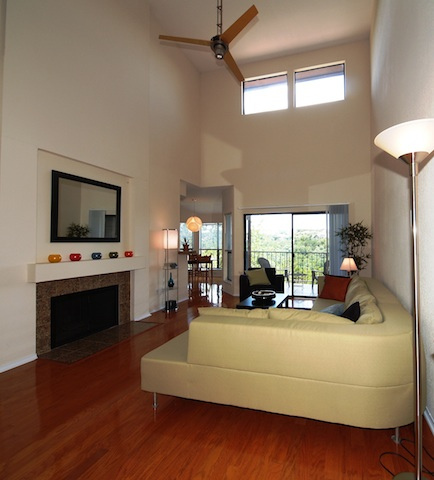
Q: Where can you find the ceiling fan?
A: Ceiling.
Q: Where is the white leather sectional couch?
A: Next to the wall.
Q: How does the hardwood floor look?
A: Shiny.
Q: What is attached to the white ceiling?
A: A ceiling fan.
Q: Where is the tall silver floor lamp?
A: Next to the couch.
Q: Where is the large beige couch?
A: Next to the wall.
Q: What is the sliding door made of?
A: Glass.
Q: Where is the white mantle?
A: Above the fireplace.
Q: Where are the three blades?
A: On the ceiling fan.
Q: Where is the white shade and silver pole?
A: On the floor lamp.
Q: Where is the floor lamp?
A: Next to the couch.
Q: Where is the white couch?
A: In the living room.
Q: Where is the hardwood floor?
A: In the living room.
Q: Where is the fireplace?
A: Under the mirror.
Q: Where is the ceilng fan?
A: Up high.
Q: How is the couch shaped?
A: L shaped.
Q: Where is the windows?
A: Near the ceiling fan.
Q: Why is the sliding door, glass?
A: To see out of it.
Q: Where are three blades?
A: On the ceiling fan.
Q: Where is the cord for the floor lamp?
A: On the floor.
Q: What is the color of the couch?
A: White.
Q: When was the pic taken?
A: During the day.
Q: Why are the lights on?
A: To brighten the room.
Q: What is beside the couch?
A: A lampstand.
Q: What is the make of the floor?
A: Wood.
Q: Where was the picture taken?
A: In the living room.